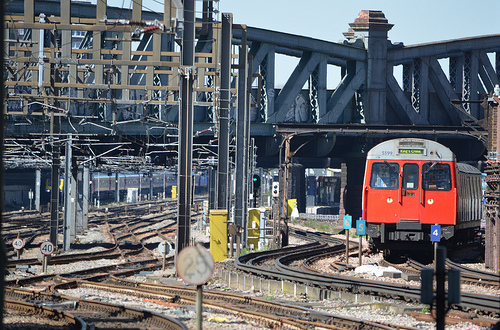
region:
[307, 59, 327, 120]
grey steel building support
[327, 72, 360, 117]
grey steel building support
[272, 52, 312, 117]
grey steel building support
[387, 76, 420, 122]
grey steel building support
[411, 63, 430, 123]
grey steel building support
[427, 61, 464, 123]
grey steel building support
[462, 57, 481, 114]
grey steel building support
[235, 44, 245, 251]
grey steel building support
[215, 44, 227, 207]
grey steel building support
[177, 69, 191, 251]
grey steel building support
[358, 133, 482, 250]
a red train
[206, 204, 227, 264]
a yellow box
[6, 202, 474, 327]
the rail road tracks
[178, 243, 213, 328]
a sign on the ground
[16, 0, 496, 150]
a cement bridge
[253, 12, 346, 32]
a clear sky behind the bridge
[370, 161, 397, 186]
the window of the train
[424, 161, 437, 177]
a windshield wiper on the train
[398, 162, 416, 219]
the door of the train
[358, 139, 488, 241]
a white and red train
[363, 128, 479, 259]
commuter train on the tracks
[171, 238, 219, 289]
number 25 on a pole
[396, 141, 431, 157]
electric sign on a train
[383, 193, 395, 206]
headlights on a commuter train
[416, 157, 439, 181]
windshield wipers on the train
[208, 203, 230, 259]
electric box on the train tracks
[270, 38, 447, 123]
beams above the train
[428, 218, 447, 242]
number four on a pole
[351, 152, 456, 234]
red paint on a train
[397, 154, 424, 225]
door to the train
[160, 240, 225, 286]
the sign is round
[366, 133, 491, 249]
the train is red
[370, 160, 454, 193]
the windshield has wipers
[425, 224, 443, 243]
the sign is blue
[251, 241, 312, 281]
the tracks are metal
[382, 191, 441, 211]
the train has headlights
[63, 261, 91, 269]
the gravel is gray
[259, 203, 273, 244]
the pole is blue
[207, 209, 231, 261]
the box is yellow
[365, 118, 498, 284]
the train is on tracks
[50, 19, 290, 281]
a very industrial setting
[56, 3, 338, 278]
many types of steel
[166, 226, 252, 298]
the speed limit is 25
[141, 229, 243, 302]
the sign is round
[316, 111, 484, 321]
front of the train is red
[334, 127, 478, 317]
three windows on front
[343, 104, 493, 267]
the engine has a driver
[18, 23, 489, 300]
the train is in the yard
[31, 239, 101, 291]
this sign says 40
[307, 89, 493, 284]
train is on the tracks